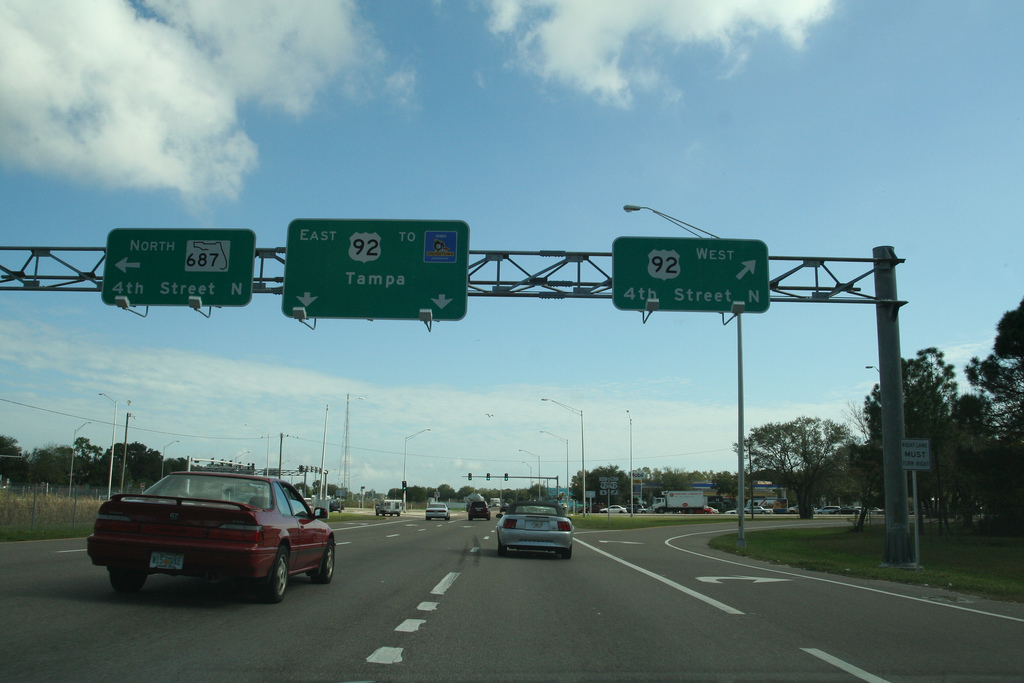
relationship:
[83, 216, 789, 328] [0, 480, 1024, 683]
signs hang over multilanehighway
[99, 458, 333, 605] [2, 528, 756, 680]
car driving on road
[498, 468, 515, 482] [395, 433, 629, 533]
light in distance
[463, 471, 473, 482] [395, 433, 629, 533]
light in distance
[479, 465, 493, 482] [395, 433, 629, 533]
light in distance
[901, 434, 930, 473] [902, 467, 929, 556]
sign on pole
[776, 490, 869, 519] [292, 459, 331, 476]
vehicle at light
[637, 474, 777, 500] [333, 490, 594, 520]
gas station at intersection